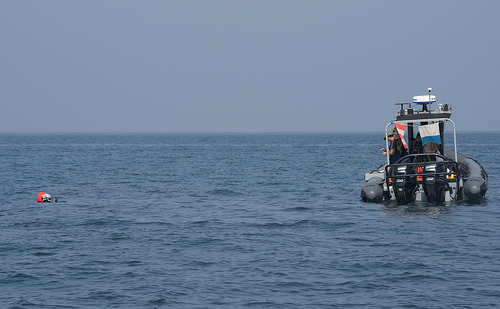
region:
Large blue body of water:
[4, 128, 495, 308]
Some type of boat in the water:
[354, 79, 499, 220]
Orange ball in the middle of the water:
[24, 175, 56, 217]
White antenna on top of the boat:
[403, 85, 453, 120]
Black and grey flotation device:
[348, 132, 495, 221]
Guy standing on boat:
[370, 124, 426, 174]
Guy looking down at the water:
[379, 110, 414, 177]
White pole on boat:
[364, 98, 491, 207]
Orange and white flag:
[381, 115, 417, 161]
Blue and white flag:
[407, 112, 449, 162]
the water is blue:
[132, 177, 304, 274]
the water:
[120, 210, 251, 280]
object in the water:
[34, 179, 64, 202]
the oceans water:
[120, 139, 271, 205]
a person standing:
[377, 125, 401, 155]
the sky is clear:
[113, 31, 311, 106]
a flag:
[391, 123, 408, 146]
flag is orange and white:
[390, 122, 415, 152]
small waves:
[252, 216, 313, 241]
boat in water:
[367, 78, 482, 223]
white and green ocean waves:
[124, 183, 168, 218]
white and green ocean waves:
[248, 156, 289, 201]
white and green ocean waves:
[291, 229, 358, 280]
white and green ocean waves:
[348, 228, 428, 285]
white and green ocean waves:
[120, 236, 181, 288]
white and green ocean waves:
[148, 172, 209, 234]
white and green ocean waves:
[224, 153, 289, 210]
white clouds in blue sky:
[22, 22, 79, 74]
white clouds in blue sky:
[207, 21, 264, 69]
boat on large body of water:
[362, 85, 484, 210]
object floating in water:
[30, 185, 67, 210]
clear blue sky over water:
[2, 6, 492, 136]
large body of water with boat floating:
[7, 137, 499, 296]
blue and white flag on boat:
[416, 123, 444, 148]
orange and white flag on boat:
[390, 123, 410, 148]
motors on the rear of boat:
[385, 178, 458, 208]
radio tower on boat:
[396, 100, 411, 118]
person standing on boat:
[380, 132, 398, 160]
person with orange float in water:
[35, 188, 56, 204]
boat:
[370, 82, 427, 223]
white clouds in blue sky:
[4, 13, 46, 50]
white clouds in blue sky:
[18, 19, 129, 140]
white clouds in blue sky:
[108, 59, 163, 103]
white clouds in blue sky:
[155, 51, 232, 105]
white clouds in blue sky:
[217, 35, 287, 132]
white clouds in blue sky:
[308, 25, 339, 93]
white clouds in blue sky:
[348, 29, 386, 76]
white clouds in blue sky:
[312, 42, 374, 57]